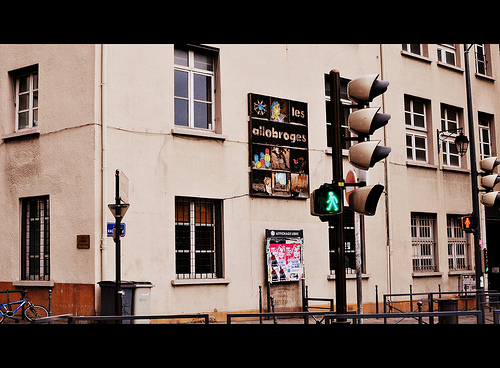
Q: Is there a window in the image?
A: Yes, there is a window.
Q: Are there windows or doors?
A: Yes, there is a window.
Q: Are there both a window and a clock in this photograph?
A: No, there is a window but no clocks.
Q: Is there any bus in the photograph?
A: No, there are no buses.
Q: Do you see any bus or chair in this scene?
A: No, there are no buses or chairs.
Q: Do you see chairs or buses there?
A: No, there are no buses or chairs.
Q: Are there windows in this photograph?
A: Yes, there is a window.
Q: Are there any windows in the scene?
A: Yes, there is a window.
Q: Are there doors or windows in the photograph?
A: Yes, there is a window.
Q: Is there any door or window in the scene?
A: Yes, there is a window.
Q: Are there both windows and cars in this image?
A: No, there is a window but no cars.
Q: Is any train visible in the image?
A: No, there are no trains.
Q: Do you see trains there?
A: No, there are no trains.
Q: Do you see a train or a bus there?
A: No, there are no trains or buses.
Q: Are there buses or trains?
A: No, there are no trains or buses.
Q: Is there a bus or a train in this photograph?
A: No, there are no trains or buses.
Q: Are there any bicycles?
A: Yes, there is a bicycle.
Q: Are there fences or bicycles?
A: Yes, there is a bicycle.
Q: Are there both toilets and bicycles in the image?
A: No, there is a bicycle but no toilets.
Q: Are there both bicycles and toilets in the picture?
A: No, there is a bicycle but no toilets.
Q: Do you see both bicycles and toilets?
A: No, there is a bicycle but no toilets.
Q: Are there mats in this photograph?
A: No, there are no mats.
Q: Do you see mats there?
A: No, there are no mats.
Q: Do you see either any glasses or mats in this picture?
A: No, there are no mats or glasses.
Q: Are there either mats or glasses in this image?
A: No, there are no mats or glasses.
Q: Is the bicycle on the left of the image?
A: Yes, the bicycle is on the left of the image.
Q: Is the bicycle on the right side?
A: No, the bicycle is on the left of the image.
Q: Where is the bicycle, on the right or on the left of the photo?
A: The bicycle is on the left of the image.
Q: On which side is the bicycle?
A: The bicycle is on the left of the image.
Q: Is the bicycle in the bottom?
A: Yes, the bicycle is in the bottom of the image.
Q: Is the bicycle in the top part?
A: No, the bicycle is in the bottom of the image.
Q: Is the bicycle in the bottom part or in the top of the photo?
A: The bicycle is in the bottom of the image.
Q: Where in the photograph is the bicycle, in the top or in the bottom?
A: The bicycle is in the bottom of the image.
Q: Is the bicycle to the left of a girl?
A: No, the bicycle is to the left of the trash bin.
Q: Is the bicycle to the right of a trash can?
A: No, the bicycle is to the left of a trash can.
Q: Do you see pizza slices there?
A: No, there are no pizza slices.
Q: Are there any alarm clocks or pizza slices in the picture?
A: No, there are no pizza slices or alarm clocks.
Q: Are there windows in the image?
A: Yes, there is a window.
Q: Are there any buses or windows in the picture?
A: Yes, there is a window.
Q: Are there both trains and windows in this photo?
A: No, there is a window but no trains.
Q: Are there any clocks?
A: No, there are no clocks.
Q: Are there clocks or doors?
A: No, there are no clocks or doors.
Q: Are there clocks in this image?
A: No, there are no clocks.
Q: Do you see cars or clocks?
A: No, there are no clocks or cars.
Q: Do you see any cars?
A: No, there are no cars.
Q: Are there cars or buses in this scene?
A: No, there are no cars or buses.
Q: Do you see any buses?
A: No, there are no buses.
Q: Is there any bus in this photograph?
A: No, there are no buses.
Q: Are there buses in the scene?
A: No, there are no buses.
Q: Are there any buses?
A: No, there are no buses.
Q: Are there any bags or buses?
A: No, there are no buses or bags.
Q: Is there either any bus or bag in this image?
A: No, there are no buses or bags.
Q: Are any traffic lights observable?
A: Yes, there is a traffic light.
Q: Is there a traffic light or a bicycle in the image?
A: Yes, there is a traffic light.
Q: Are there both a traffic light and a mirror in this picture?
A: No, there is a traffic light but no mirrors.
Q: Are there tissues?
A: No, there are no tissues.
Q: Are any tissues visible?
A: No, there are no tissues.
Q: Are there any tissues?
A: No, there are no tissues.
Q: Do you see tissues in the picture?
A: No, there are no tissues.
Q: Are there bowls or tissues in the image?
A: No, there are no tissues or bowls.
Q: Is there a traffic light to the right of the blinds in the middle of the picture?
A: Yes, there is a traffic light to the right of the blinds.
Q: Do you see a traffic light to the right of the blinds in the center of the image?
A: Yes, there is a traffic light to the right of the blinds.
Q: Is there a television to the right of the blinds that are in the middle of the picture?
A: No, there is a traffic light to the right of the blinds.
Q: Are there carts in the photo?
A: No, there are no carts.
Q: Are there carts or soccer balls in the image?
A: No, there are no carts or soccer balls.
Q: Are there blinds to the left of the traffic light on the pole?
A: Yes, there are blinds to the left of the traffic light.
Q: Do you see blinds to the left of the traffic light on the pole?
A: Yes, there are blinds to the left of the traffic light.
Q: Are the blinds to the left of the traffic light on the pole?
A: Yes, the blinds are to the left of the traffic light.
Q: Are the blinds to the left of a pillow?
A: No, the blinds are to the left of the traffic light.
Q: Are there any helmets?
A: No, there are no helmets.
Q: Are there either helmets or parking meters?
A: No, there are no helmets or parking meters.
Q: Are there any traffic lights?
A: Yes, there is a traffic light.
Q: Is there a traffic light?
A: Yes, there is a traffic light.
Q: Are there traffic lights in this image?
A: Yes, there is a traffic light.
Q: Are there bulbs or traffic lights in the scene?
A: Yes, there is a traffic light.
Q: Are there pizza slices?
A: No, there are no pizza slices.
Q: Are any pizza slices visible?
A: No, there are no pizza slices.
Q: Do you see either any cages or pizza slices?
A: No, there are no pizza slices or cages.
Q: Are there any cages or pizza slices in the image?
A: No, there are no pizza slices or cages.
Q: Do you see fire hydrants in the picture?
A: No, there are no fire hydrants.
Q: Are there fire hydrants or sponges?
A: No, there are no fire hydrants or sponges.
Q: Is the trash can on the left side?
A: Yes, the trash can is on the left of the image.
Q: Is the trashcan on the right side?
A: No, the trashcan is on the left of the image.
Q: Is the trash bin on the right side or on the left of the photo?
A: The trash bin is on the left of the image.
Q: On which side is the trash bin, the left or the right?
A: The trash bin is on the left of the image.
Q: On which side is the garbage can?
A: The garbage can is on the left of the image.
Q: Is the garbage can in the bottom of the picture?
A: Yes, the garbage can is in the bottom of the image.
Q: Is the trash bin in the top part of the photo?
A: No, the trash bin is in the bottom of the image.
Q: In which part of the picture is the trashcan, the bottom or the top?
A: The trashcan is in the bottom of the image.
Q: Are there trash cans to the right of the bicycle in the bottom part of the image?
A: Yes, there is a trash can to the right of the bicycle.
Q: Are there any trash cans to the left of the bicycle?
A: No, the trash can is to the right of the bicycle.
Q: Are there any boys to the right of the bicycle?
A: No, there is a trash can to the right of the bicycle.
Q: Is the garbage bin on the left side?
A: Yes, the garbage bin is on the left of the image.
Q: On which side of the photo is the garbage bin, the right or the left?
A: The garbage bin is on the left of the image.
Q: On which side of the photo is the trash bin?
A: The trash bin is on the left of the image.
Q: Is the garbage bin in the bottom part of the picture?
A: Yes, the garbage bin is in the bottom of the image.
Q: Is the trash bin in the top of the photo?
A: No, the trash bin is in the bottom of the image.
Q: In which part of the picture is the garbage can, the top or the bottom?
A: The garbage can is in the bottom of the image.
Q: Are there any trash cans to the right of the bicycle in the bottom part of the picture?
A: Yes, there is a trash can to the right of the bicycle.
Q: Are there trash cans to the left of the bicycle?
A: No, the trash can is to the right of the bicycle.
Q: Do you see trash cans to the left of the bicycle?
A: No, the trash can is to the right of the bicycle.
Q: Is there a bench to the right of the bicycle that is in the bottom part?
A: No, there is a trash can to the right of the bicycle.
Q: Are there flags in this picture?
A: No, there are no flags.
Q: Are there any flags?
A: No, there are no flags.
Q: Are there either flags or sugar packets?
A: No, there are no flags or sugar packets.